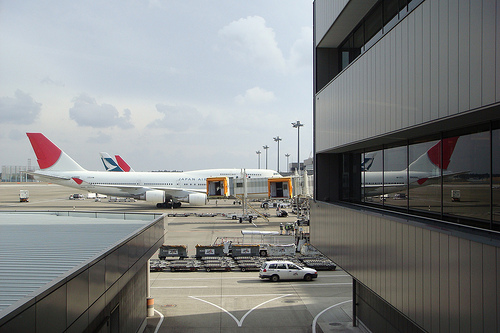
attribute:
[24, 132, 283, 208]
plane — large, white, red, parked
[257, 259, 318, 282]
car — white, driving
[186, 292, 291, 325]
triangle — white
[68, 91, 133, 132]
cloud — puffy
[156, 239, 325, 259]
carts — luggage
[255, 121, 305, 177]
poles — tall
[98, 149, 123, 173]
tail — blue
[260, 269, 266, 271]
tail light — red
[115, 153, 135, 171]
tail — red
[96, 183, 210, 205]
wing — large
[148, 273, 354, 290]
lines — white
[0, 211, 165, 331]
building — gray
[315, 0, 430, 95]
windows — large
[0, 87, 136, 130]
clouds — grey, dark, large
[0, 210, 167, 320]
roof — white, flat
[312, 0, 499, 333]
building — dark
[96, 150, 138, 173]
airplanes — parked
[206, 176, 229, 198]
opening — square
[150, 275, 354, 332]
markings — white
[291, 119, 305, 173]
light — tall